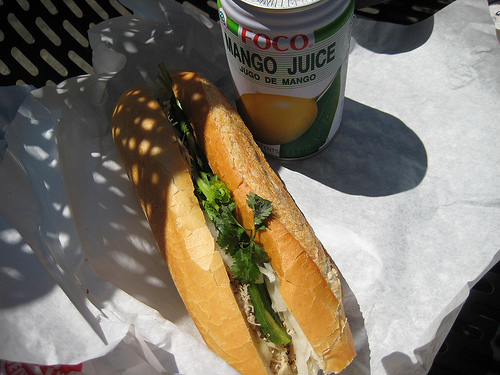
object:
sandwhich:
[110, 71, 355, 374]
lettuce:
[212, 194, 273, 285]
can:
[216, 2, 354, 162]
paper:
[0, 0, 499, 374]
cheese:
[233, 275, 317, 373]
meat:
[226, 255, 297, 373]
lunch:
[108, 0, 356, 374]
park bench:
[2, 1, 499, 371]